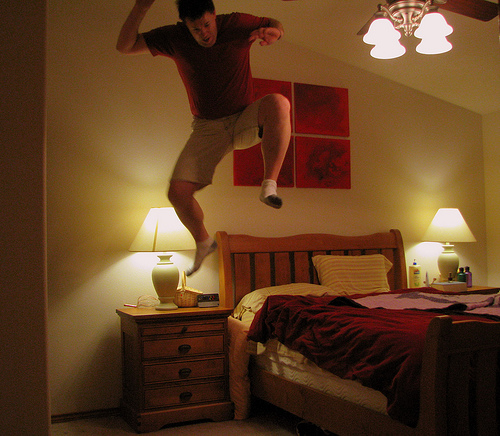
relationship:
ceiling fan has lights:
[350, 0, 500, 61] [363, 12, 455, 60]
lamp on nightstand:
[422, 205, 476, 291] [431, 281, 500, 301]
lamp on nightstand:
[128, 204, 194, 313] [113, 297, 233, 432]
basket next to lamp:
[173, 269, 203, 310] [128, 204, 194, 313]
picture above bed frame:
[233, 78, 353, 192] [208, 227, 499, 434]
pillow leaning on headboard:
[307, 253, 393, 295] [210, 231, 414, 308]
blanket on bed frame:
[353, 289, 498, 316] [208, 227, 499, 434]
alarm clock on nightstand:
[194, 292, 222, 309] [113, 297, 233, 432]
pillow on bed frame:
[307, 253, 393, 295] [208, 227, 499, 434]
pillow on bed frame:
[239, 275, 338, 313] [208, 227, 499, 434]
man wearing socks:
[114, 1, 292, 277] [182, 177, 283, 280]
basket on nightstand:
[173, 269, 203, 310] [113, 297, 233, 432]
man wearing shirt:
[114, 1, 292, 277] [138, 12, 273, 121]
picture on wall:
[233, 78, 353, 192] [44, 0, 481, 419]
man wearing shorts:
[114, 1, 292, 277] [167, 93, 263, 188]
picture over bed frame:
[233, 78, 353, 192] [208, 227, 499, 434]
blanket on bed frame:
[246, 291, 494, 423] [208, 227, 499, 434]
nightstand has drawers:
[113, 297, 233, 432] [138, 319, 224, 413]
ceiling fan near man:
[350, 0, 500, 61] [114, 1, 292, 277]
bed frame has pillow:
[208, 227, 499, 434] [307, 253, 393, 295]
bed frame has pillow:
[208, 227, 499, 434] [239, 275, 338, 313]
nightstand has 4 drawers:
[113, 297, 233, 432] [138, 319, 224, 413]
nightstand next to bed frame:
[431, 281, 500, 301] [208, 227, 499, 434]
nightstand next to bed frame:
[113, 297, 233, 432] [208, 227, 499, 434]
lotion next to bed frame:
[407, 260, 420, 287] [208, 227, 499, 434]